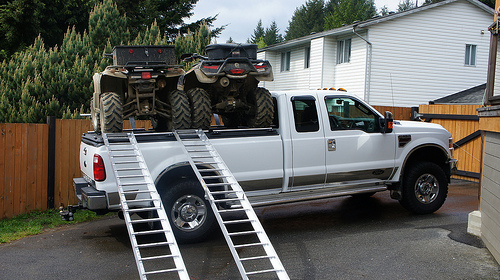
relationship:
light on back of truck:
[91, 153, 108, 181] [73, 88, 458, 243]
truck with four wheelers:
[49, 82, 459, 246] [90, 43, 276, 135]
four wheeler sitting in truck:
[87, 43, 191, 138] [73, 88, 458, 243]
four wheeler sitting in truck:
[180, 40, 274, 130] [73, 88, 458, 243]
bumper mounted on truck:
[73, 176, 106, 208] [73, 88, 458, 243]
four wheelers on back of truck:
[90, 43, 276, 135] [73, 88, 458, 243]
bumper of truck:
[73, 176, 106, 208] [71, 88, 448, 231]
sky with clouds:
[197, 0, 279, 42] [195, 0, 274, 31]